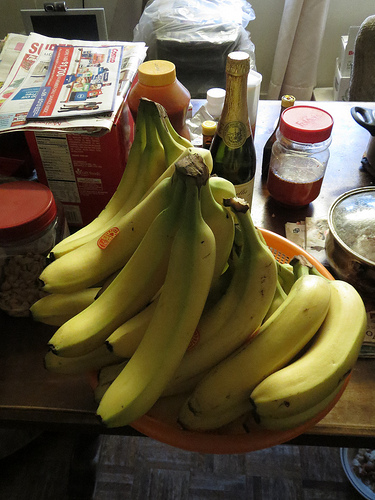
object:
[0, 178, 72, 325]
plastic container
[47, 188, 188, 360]
bananas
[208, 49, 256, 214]
bottle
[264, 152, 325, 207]
liquid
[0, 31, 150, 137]
news papers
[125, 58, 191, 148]
bottle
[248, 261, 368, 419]
bananas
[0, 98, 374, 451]
table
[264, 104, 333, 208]
item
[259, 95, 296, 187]
item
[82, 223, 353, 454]
bowl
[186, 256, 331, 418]
banana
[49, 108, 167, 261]
banana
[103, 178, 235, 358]
banana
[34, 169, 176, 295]
banana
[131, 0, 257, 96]
sack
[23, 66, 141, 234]
box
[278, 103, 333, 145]
cap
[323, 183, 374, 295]
pot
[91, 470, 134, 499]
tile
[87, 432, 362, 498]
floor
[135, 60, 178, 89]
lid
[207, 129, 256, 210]
champagne